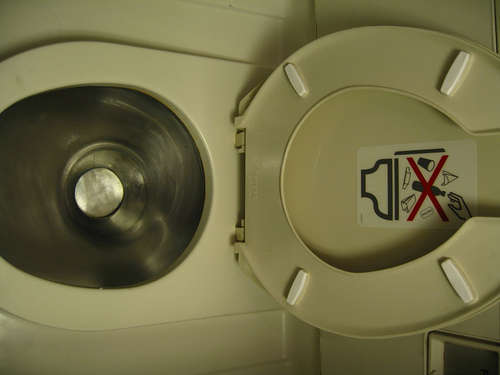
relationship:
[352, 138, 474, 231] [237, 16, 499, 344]
picture inside of lid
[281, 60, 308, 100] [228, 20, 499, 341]
bumper inside of toilet lid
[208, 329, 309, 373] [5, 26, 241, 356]
white wall behind toilet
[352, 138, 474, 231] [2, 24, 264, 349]
picture on toilet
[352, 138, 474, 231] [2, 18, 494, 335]
picture on toilet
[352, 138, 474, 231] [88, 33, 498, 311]
picture on inside of toilet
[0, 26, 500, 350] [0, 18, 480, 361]
toilet in an airplane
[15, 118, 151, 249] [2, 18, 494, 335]
inside of toilet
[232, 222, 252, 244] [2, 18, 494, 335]
screw holding toilet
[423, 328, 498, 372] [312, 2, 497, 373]
trash can on wall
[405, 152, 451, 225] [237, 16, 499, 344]
red x on lid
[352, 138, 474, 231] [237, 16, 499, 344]
picture on lid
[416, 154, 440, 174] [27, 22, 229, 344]
cup are on seat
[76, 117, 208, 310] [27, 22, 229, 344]
bottle on seat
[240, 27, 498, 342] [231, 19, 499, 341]
underside of toilet seat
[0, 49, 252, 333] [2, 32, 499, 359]
bowl of toilet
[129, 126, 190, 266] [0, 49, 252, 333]
metal inside bowl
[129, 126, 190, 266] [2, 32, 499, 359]
metal inside toilet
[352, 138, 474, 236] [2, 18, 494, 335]
picture on toilet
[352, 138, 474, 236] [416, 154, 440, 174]
picture of cup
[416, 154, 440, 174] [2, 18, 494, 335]
cup on toilet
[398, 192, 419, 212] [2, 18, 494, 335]
paper bag on toilet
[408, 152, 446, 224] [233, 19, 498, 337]
red x on toilet backing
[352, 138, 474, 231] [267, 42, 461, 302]
picture on lid